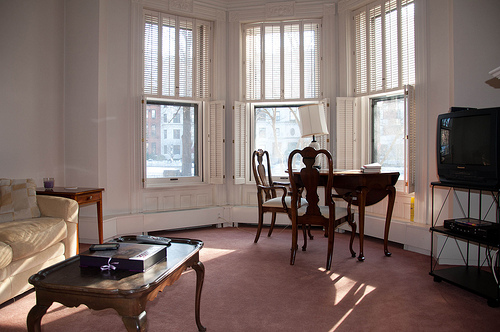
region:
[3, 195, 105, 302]
Beige couch by a wall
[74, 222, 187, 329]
Brown coffee table on a floor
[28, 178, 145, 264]
Brown end table by a couch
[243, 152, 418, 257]
Two chairs by a table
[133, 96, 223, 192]
Window in a room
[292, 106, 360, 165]
Lamp on a table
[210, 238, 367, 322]
Tan carpet on a floor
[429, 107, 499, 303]
TV on a stand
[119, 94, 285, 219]
Open shutters by a window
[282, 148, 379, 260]
Brown chair by a table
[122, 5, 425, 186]
Bright, sunny, bay windows.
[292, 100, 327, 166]
Lamp on table with crooked white shade.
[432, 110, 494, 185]
Television on stand.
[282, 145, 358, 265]
Open back upholstered dining room chair.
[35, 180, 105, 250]
Lightwood end table with drawer.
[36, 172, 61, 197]
Candle on end table.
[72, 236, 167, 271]
Game playing device with remote.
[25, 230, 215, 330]
Vintage coffee table, with no spill edge.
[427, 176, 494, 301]
Television and cable box stand.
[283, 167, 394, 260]
Wooden dining room table.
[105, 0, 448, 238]
a curved wall with windows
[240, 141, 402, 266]
early American furniture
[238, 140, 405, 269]
two chairs and a table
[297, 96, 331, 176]
ceramic lamp with white lampshade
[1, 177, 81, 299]
a white sofa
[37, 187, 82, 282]
sofa arm topped with round portion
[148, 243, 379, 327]
the shadow of the table and chairs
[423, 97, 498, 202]
a very old TV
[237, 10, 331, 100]
window with shutters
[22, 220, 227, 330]
coffee table with remote control on it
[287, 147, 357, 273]
Fancy looking wooden chair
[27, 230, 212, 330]
Wooden coffee table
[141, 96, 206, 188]
Window that is closed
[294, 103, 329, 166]
white lamp with crooked shade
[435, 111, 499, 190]
Television on a stand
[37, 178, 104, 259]
Small end table by couch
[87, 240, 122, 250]
remote control sitting on box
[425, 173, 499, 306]
black television stand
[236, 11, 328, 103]
White shutters above the window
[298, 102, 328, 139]
white tilted lampshade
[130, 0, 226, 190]
tall window with white edges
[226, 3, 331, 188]
tall center window with white edges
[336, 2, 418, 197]
tall window with white shutters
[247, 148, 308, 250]
wooden chair with white seat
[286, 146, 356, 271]
wooden chair with white seat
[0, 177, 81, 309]
white sofa with pillow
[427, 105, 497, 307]
television on stand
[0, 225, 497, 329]
rose colored rug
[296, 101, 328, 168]
white lamp shade on white base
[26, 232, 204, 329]
wooden coffee table